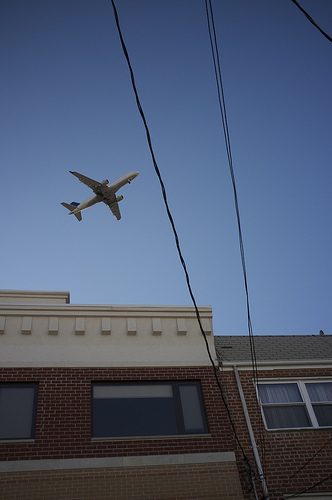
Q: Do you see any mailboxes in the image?
A: No, there are no mailboxes.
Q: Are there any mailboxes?
A: No, there are no mailboxes.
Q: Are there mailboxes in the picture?
A: No, there are no mailboxes.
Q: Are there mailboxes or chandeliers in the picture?
A: No, there are no mailboxes or chandeliers.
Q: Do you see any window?
A: Yes, there is a window.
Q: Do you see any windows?
A: Yes, there is a window.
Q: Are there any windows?
A: Yes, there is a window.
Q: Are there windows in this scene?
A: Yes, there is a window.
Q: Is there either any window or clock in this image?
A: Yes, there is a window.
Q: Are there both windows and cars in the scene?
A: No, there is a window but no cars.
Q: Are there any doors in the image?
A: No, there are no doors.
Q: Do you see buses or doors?
A: No, there are no doors or buses.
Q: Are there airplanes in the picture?
A: Yes, there is an airplane.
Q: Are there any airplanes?
A: Yes, there is an airplane.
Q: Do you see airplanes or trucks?
A: Yes, there is an airplane.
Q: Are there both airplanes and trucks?
A: No, there is an airplane but no trucks.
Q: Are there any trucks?
A: No, there are no trucks.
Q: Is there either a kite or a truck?
A: No, there are no trucks or kites.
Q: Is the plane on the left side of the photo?
A: Yes, the plane is on the left of the image.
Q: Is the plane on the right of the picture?
A: No, the plane is on the left of the image.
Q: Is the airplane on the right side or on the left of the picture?
A: The airplane is on the left of the image.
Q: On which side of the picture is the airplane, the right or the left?
A: The airplane is on the left of the image.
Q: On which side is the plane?
A: The plane is on the left of the image.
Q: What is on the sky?
A: The plane is on the sky.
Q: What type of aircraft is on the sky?
A: The aircraft is an airplane.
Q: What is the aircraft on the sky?
A: The aircraft is an airplane.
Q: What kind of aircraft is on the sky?
A: The aircraft is an airplane.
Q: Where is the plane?
A: The plane is on the sky.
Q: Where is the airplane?
A: The plane is on the sky.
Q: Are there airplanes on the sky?
A: Yes, there is an airplane on the sky.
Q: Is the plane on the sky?
A: Yes, the plane is on the sky.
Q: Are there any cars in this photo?
A: No, there are no cars.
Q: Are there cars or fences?
A: No, there are no cars or fences.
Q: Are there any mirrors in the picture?
A: No, there are no mirrors.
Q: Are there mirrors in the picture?
A: No, there are no mirrors.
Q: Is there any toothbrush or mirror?
A: No, there are no mirrors or toothbrushes.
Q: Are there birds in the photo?
A: No, there are no birds.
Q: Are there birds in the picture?
A: No, there are no birds.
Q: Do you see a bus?
A: No, there are no buses.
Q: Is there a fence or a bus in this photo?
A: No, there are no buses or fences.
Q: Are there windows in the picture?
A: Yes, there is a window.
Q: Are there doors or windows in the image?
A: Yes, there is a window.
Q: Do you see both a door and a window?
A: No, there is a window but no doors.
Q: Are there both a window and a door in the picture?
A: No, there is a window but no doors.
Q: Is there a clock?
A: No, there are no clocks.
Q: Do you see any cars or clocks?
A: No, there are no clocks or cars.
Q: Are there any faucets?
A: No, there are no faucets.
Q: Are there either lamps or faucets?
A: No, there are no faucets or lamps.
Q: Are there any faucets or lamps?
A: No, there are no faucets or lamps.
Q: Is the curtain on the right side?
A: Yes, the curtain is on the right of the image.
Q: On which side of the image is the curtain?
A: The curtain is on the right of the image.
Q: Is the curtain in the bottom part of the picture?
A: Yes, the curtain is in the bottom of the image.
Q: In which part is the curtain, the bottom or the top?
A: The curtain is in the bottom of the image.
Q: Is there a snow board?
A: No, there are no snowboards.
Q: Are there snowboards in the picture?
A: No, there are no snowboards.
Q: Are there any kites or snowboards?
A: No, there are no snowboards or kites.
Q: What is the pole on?
A: The pole is on the building.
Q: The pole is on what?
A: The pole is on the building.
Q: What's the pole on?
A: The pole is on the building.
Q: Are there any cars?
A: No, there are no cars.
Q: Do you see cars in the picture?
A: No, there are no cars.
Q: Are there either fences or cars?
A: No, there are no cars or fences.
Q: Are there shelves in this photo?
A: No, there are no shelves.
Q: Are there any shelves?
A: No, there are no shelves.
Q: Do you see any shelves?
A: No, there are no shelves.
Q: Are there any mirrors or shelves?
A: No, there are no shelves or mirrors.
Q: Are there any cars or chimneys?
A: No, there are no cars or chimneys.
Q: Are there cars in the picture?
A: No, there are no cars.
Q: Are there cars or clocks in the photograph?
A: No, there are no cars or clocks.